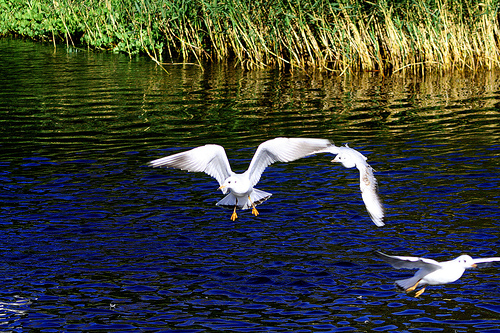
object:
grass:
[2, 3, 492, 70]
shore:
[2, 35, 498, 65]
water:
[0, 33, 500, 333]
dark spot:
[0, 150, 500, 333]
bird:
[145, 137, 333, 221]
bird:
[368, 249, 500, 297]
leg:
[233, 199, 237, 213]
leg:
[248, 196, 255, 209]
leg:
[412, 279, 421, 290]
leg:
[422, 285, 427, 291]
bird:
[300, 143, 385, 228]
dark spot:
[76, 266, 129, 288]